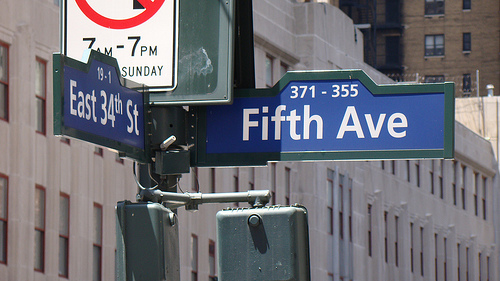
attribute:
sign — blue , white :
[45, 40, 146, 158]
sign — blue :
[232, 82, 451, 154]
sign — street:
[455, 70, 497, 130]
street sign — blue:
[196, 69, 455, 166]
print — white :
[327, 101, 416, 139]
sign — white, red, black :
[54, 1, 184, 95]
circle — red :
[78, 1, 163, 29]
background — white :
[63, 1, 177, 88]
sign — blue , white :
[236, 86, 427, 153]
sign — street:
[53, 49, 150, 163]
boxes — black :
[96, 164, 318, 272]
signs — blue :
[37, 45, 457, 172]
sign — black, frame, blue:
[31, 54, 171, 157]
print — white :
[238, 104, 325, 143]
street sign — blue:
[52, 47, 145, 161]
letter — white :
[241, 108, 260, 143]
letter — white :
[258, 106, 268, 138]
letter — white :
[270, 104, 285, 143]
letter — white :
[285, 109, 302, 142]